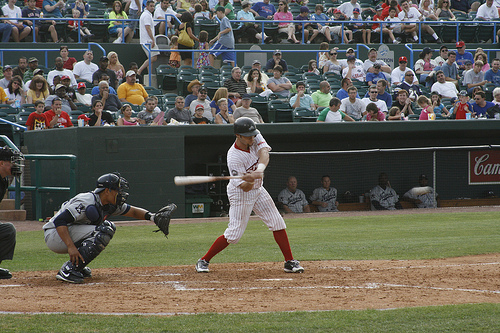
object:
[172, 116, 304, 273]
batter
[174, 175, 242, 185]
bat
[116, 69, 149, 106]
man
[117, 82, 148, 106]
shirt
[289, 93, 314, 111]
shirt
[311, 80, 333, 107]
man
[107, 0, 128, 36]
person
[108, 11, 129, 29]
shirt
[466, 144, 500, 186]
advertisement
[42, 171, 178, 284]
man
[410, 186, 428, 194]
ball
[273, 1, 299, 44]
woman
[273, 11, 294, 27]
blouse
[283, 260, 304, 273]
shoe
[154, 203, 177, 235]
baseball glove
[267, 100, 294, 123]
stadium seat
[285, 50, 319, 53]
pole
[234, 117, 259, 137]
baseball hat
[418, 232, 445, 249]
grass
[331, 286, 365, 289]
line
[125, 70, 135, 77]
baseball cap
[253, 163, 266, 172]
wristband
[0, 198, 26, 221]
stairway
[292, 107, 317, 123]
stadium seat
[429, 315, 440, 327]
grass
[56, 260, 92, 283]
tennis shoe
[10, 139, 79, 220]
stair rail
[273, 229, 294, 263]
sock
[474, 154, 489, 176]
capital letter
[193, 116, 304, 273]
man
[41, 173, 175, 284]
catcher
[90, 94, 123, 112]
shirt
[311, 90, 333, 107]
shirt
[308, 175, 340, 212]
players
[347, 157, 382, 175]
dugout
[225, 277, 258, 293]
batters box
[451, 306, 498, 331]
field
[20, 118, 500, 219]
bleachers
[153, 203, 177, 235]
mitt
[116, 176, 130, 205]
facemask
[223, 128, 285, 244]
uniform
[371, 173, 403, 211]
players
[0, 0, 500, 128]
crowd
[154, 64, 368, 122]
seats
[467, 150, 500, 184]
sign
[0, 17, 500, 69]
stands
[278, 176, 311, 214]
players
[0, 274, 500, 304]
dirt